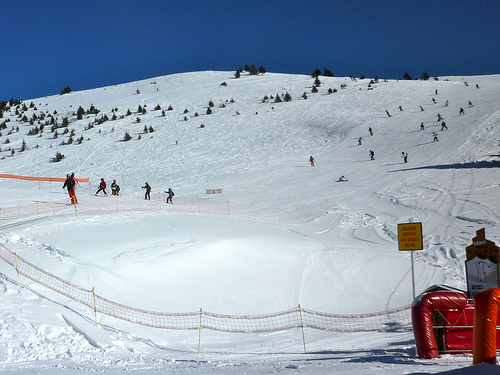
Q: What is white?
A: Snow.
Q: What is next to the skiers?
A: Fence.